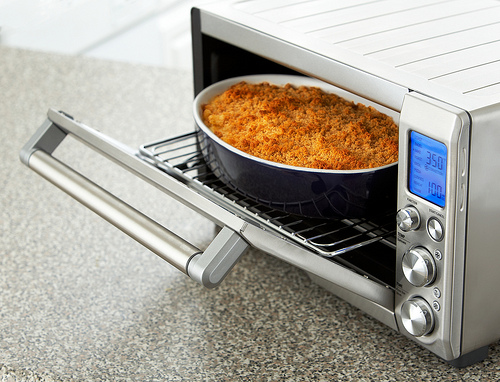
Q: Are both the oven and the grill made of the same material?
A: Yes, both the oven and the grill are made of metal.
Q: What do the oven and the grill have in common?
A: The material, both the oven and the grill are metallic.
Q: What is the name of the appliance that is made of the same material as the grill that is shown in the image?
A: The appliance is an oven.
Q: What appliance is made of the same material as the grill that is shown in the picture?
A: The oven is made of the same material as the grill.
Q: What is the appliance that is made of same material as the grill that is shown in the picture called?
A: The appliance is an oven.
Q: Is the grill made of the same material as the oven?
A: Yes, both the grill and the oven are made of metal.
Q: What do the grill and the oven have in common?
A: The material, both the grill and the oven are metallic.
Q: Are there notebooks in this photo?
A: No, there are no notebooks.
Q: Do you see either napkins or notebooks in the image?
A: No, there are no notebooks or napkins.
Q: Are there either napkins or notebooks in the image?
A: No, there are no notebooks or napkins.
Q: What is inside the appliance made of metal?
A: The dish is inside the oven.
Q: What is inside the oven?
A: The dish is inside the oven.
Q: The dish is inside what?
A: The dish is inside the oven.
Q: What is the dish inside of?
A: The dish is inside the oven.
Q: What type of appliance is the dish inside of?
A: The dish is inside the oven.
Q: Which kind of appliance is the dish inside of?
A: The dish is inside the oven.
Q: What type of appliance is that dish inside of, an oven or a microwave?
A: The dish is inside an oven.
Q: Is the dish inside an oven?
A: Yes, the dish is inside an oven.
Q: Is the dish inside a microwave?
A: No, the dish is inside an oven.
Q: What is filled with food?
A: The dish is filled with food.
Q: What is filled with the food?
A: The dish is filled with food.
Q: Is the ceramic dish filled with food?
A: Yes, the dish is filled with food.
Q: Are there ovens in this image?
A: Yes, there is an oven.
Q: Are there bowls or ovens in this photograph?
A: Yes, there is an oven.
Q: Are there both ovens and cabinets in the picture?
A: No, there is an oven but no cabinets.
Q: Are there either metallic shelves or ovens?
A: Yes, there is a metal oven.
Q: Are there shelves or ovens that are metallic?
A: Yes, the oven is metallic.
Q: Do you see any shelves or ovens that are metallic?
A: Yes, the oven is metallic.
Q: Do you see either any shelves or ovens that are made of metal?
A: Yes, the oven is made of metal.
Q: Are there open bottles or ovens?
A: Yes, there is an open oven.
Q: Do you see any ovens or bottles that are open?
A: Yes, the oven is open.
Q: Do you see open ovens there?
A: Yes, there is an open oven.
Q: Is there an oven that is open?
A: Yes, there is an oven that is open.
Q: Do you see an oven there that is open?
A: Yes, there is an oven that is open.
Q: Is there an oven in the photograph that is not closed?
A: Yes, there is a open oven.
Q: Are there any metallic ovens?
A: Yes, there is a metal oven.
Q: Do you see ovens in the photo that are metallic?
A: Yes, there is an oven that is metallic.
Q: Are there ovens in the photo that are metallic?
A: Yes, there is an oven that is metallic.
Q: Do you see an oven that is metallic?
A: Yes, there is an oven that is metallic.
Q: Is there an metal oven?
A: Yes, there is an oven that is made of metal.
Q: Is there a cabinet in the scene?
A: No, there are no cabinets.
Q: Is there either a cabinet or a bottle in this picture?
A: No, there are no cabinets or bottles.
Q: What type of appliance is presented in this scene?
A: The appliance is an oven.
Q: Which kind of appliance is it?
A: The appliance is an oven.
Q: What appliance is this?
A: This is an oven.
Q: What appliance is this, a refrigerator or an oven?
A: This is an oven.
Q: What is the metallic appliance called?
A: The appliance is an oven.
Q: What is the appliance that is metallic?
A: The appliance is an oven.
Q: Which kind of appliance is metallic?
A: The appliance is an oven.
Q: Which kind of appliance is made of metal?
A: The appliance is an oven.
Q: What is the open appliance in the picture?
A: The appliance is an oven.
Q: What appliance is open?
A: The appliance is an oven.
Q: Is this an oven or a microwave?
A: This is an oven.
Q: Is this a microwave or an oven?
A: This is an oven.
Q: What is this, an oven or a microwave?
A: This is an oven.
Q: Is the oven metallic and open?
A: Yes, the oven is metallic and open.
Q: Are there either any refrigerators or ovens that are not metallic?
A: No, there is an oven but it is metallic.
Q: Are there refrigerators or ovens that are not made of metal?
A: No, there is an oven but it is made of metal.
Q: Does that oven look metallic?
A: Yes, the oven is metallic.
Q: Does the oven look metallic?
A: Yes, the oven is metallic.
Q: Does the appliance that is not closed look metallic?
A: Yes, the oven is metallic.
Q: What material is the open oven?
A: The oven is made of metal.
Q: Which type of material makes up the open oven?
A: The oven is made of metal.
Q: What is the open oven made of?
A: The oven is made of metal.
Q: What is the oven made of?
A: The oven is made of metal.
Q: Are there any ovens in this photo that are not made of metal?
A: No, there is an oven but it is made of metal.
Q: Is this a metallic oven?
A: Yes, this is a metallic oven.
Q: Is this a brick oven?
A: No, this is a metallic oven.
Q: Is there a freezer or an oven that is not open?
A: No, there is an oven but it is open.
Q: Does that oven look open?
A: Yes, the oven is open.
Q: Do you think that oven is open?
A: Yes, the oven is open.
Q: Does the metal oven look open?
A: Yes, the oven is open.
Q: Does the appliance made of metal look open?
A: Yes, the oven is open.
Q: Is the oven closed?
A: No, the oven is open.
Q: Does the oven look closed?
A: No, the oven is open.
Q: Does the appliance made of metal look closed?
A: No, the oven is open.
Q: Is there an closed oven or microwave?
A: No, there is an oven but it is open.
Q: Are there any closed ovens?
A: No, there is an oven but it is open.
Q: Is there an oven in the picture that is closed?
A: No, there is an oven but it is open.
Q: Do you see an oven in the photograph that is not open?
A: No, there is an oven but it is open.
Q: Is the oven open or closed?
A: The oven is open.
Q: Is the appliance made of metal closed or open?
A: The oven is open.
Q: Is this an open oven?
A: Yes, this is an open oven.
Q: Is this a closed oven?
A: No, this is an open oven.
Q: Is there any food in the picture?
A: Yes, there is food.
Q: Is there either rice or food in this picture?
A: Yes, there is food.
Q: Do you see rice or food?
A: Yes, there is food.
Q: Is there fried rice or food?
A: Yes, there is fried food.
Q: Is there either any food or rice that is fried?
A: Yes, the food is fried.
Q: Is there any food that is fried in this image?
A: Yes, there is fried food.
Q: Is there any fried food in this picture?
A: Yes, there is fried food.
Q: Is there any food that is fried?
A: Yes, there is food that is fried.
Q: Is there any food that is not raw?
A: Yes, there is fried food.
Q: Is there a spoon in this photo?
A: No, there are no spoons.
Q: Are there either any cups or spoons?
A: No, there are no spoons or cups.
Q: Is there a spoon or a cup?
A: No, there are no spoons or cups.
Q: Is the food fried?
A: Yes, the food is fried.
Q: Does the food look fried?
A: Yes, the food is fried.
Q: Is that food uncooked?
A: No, the food is fried.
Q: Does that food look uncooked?
A: No, the food is fried.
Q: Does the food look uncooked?
A: No, the food is fried.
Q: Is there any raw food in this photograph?
A: No, there is food but it is fried.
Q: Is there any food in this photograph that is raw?
A: No, there is food but it is fried.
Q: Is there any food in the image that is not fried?
A: No, there is food but it is fried.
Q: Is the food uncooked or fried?
A: The food is fried.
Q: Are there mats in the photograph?
A: No, there are no mats.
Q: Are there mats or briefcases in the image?
A: No, there are no mats or briefcases.